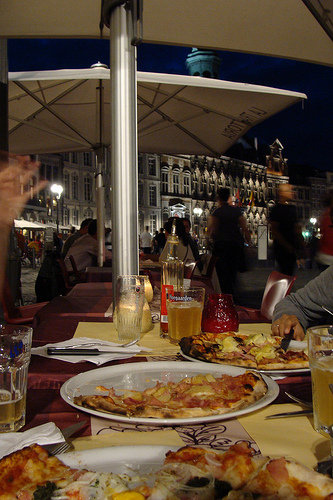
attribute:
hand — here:
[0, 146, 53, 215]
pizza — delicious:
[66, 367, 269, 418]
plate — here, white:
[70, 364, 219, 389]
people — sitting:
[59, 214, 203, 274]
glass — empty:
[111, 274, 147, 347]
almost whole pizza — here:
[179, 328, 317, 367]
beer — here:
[154, 279, 208, 341]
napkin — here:
[29, 335, 157, 367]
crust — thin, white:
[79, 398, 165, 421]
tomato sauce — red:
[4, 461, 20, 495]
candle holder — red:
[197, 288, 239, 333]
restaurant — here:
[2, 156, 332, 498]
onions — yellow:
[160, 475, 221, 493]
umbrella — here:
[6, 62, 320, 161]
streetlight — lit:
[21, 182, 74, 217]